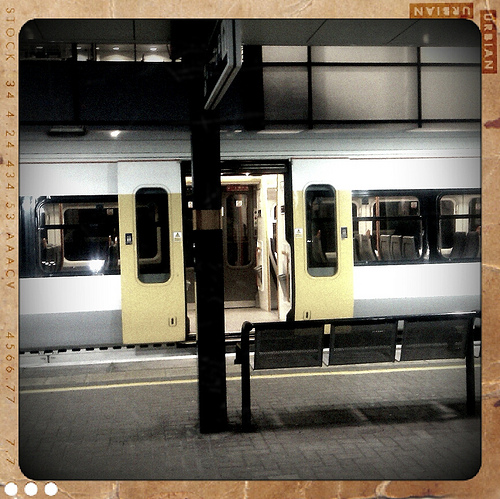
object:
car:
[17, 120, 489, 361]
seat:
[400, 235, 421, 260]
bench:
[232, 309, 484, 431]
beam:
[21, 349, 195, 369]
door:
[289, 155, 355, 352]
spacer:
[23, 339, 199, 373]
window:
[351, 187, 485, 266]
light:
[109, 128, 123, 140]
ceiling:
[20, 120, 482, 136]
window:
[32, 195, 125, 280]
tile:
[71, 384, 86, 398]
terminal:
[18, 18, 480, 479]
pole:
[188, 130, 229, 443]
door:
[117, 156, 187, 346]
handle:
[123, 232, 134, 247]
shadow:
[223, 398, 484, 433]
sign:
[201, 19, 233, 110]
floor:
[187, 305, 277, 335]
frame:
[245, 45, 486, 130]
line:
[19, 361, 480, 397]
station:
[20, 17, 480, 481]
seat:
[389, 234, 403, 261]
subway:
[20, 124, 482, 346]